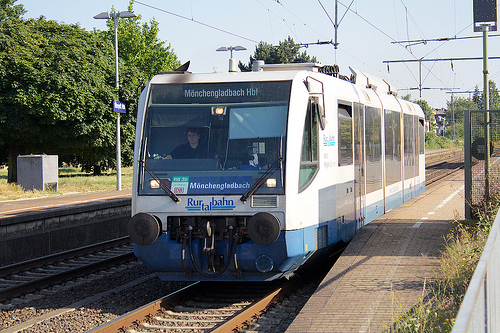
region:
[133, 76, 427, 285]
blue and white train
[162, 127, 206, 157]
person driving the train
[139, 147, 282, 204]
windshield wipers on the train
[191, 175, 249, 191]
white lettering on blue background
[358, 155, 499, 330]
white line painted on the sidewalk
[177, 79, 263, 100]
white lettering on black background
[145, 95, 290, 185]
window on a train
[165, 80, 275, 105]
sign on a train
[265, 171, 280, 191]
light on a train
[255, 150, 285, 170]
wiper on a train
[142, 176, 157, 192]
light on a train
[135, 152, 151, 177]
wiper on a train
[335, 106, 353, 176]
window on a train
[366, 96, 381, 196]
window on a train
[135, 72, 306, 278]
train on a track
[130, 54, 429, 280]
Train moving on tracks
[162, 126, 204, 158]
Man inside a train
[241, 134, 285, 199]
Windshield wiper on a train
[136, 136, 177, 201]
Windshield wiper on a train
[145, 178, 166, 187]
Headlight on a train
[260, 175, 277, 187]
Headlight on a train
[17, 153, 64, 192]
Gray square metal box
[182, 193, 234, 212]
Words on the front of a train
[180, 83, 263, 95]
Sign on the top of a train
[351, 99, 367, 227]
Door in the side of a train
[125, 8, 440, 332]
train on a track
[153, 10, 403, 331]
train on a train track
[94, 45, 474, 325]
trackw ith train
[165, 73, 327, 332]
train track with train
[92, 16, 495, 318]
a passenger train on train tracks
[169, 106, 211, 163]
a person driving the train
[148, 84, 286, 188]
window on the train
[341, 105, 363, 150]
window on train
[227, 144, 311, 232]
window shield wiper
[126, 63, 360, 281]
a blue and white train engine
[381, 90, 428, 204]
a white and blue passenger car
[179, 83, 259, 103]
a train electronic destination sign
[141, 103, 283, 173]
a train front windshield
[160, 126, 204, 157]
a train engineer driving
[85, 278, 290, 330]
a set of train tracks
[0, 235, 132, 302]
a set of train tracks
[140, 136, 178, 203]
a train windshield wiper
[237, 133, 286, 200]
a train windshield wiper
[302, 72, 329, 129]
a train side mirror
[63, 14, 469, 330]
this is a train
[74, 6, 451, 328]
train on the tracks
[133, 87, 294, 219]
front window on train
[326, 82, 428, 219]
row of windows on train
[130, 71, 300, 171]
Front window of a train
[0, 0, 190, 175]
Green leaves on the trees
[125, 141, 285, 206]
Two black windshield wipers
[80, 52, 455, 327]
A white and blue train on tracks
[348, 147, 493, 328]
White line on the ground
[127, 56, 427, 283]
train riding on train tracks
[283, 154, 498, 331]
brown brick walkway with white line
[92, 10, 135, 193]
two lamps on top of metal pole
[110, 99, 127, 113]
blue and white sign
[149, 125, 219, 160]
man wearing a black shirt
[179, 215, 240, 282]
black piping hanging on front of train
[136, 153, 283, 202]
two black windshield wipers